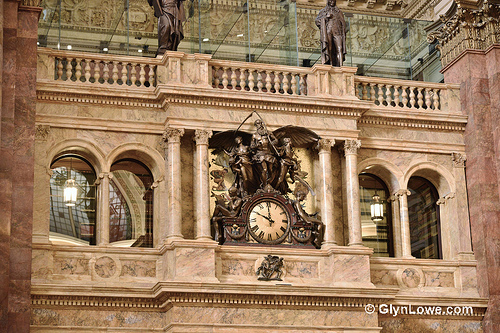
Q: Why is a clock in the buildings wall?
A: It's a clock tower.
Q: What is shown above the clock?
A: A balcony.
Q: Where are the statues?
A: On the balcony railing.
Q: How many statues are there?
A: Two.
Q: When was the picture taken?
A: During daytime.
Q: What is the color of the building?
A: Beige brown.